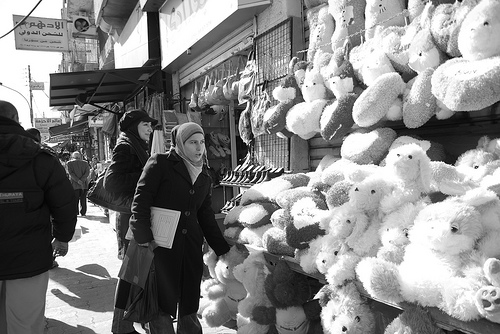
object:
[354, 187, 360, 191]
toy nose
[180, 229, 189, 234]
buttons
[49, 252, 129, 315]
shadow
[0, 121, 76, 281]
coat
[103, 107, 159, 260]
woman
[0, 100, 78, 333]
man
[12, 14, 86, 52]
sign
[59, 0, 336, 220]
building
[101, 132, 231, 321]
coat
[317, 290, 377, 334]
teddy bear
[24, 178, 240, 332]
ground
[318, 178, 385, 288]
black eyes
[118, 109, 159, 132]
hat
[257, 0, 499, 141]
row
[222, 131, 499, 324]
row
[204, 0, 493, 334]
stuffed animal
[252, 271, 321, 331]
bear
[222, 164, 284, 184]
shoe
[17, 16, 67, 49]
writing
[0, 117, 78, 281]
jacket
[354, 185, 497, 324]
teddy bear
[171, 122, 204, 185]
scarf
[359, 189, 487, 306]
white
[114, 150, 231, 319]
jacket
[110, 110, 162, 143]
black hat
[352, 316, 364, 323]
eye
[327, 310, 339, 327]
eye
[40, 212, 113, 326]
sidewalk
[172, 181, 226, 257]
black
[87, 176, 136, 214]
back